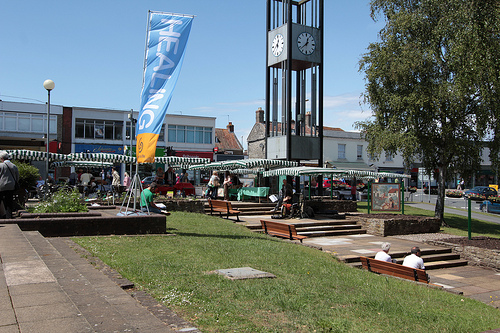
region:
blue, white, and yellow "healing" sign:
[135, 9, 194, 164]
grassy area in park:
[67, 209, 498, 331]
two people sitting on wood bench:
[359, 241, 431, 282]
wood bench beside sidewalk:
[261, 219, 307, 242]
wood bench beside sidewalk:
[208, 199, 242, 223]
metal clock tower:
[266, 0, 323, 166]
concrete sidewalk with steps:
[196, 196, 499, 307]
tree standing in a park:
[351, 1, 498, 227]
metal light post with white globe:
[42, 79, 54, 196]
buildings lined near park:
[0, 99, 499, 187]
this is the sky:
[65, 25, 110, 46]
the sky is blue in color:
[195, 40, 247, 80]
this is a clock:
[295, 31, 305, 58]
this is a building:
[326, 130, 353, 155]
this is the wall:
[323, 141, 333, 169]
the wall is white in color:
[346, 137, 355, 159]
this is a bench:
[260, 212, 305, 239]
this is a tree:
[371, 38, 443, 142]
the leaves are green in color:
[392, 34, 429, 96]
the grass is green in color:
[173, 232, 225, 257]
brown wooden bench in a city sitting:
[358, 251, 443, 287]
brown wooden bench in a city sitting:
[253, 213, 312, 245]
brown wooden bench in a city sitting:
[206, 195, 246, 220]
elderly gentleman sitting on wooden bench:
[402, 244, 425, 277]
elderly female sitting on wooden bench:
[376, 240, 393, 265]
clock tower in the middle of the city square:
[262, 0, 326, 166]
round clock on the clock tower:
[295, 31, 317, 56]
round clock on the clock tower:
[268, 32, 283, 57]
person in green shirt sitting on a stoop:
[137, 183, 159, 211]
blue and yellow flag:
[134, 6, 196, 167]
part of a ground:
[297, 285, 327, 330]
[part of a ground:
[227, 223, 252, 257]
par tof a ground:
[312, 260, 341, 300]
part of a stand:
[296, 161, 330, 214]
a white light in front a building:
[37, 73, 61, 175]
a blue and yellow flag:
[123, 5, 200, 215]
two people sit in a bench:
[358, 236, 434, 286]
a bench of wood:
[253, 213, 306, 246]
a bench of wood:
[202, 193, 242, 222]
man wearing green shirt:
[133, 176, 173, 217]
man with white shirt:
[395, 242, 426, 272]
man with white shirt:
[375, 235, 396, 265]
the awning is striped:
[259, 162, 414, 219]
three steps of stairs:
[297, 213, 367, 238]